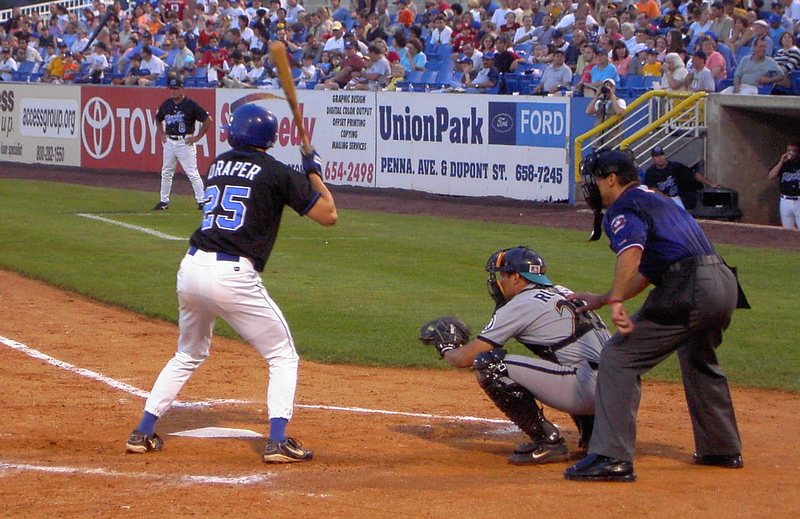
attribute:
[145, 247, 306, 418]
pants — white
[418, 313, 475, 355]
mitt — black 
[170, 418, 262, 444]
diamond — white 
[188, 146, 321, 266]
shirt — black